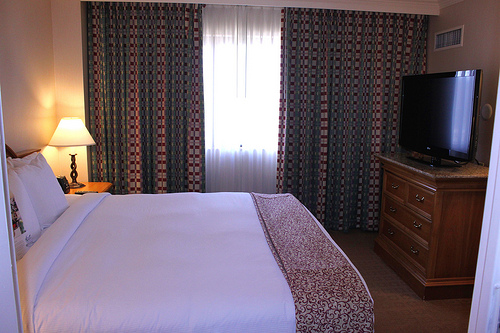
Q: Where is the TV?
A: On the dresser.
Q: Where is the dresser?
A: Under the TV.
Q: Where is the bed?
A: Against the wall.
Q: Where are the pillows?
A: On the bed.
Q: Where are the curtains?
A: On the window.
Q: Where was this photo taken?
A: Hotel room.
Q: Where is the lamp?
A: On the end table.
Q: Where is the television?
A: On top of the dresser.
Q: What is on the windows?
A: Curtains.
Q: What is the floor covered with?
A: Carpet.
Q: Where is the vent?
A: Above the television.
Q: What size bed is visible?
A: Queen.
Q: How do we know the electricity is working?
A: The lamp is on.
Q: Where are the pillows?
A: On the bed.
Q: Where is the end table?
A: Between the bed and windows.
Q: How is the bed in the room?
A: Made up.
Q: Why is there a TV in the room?
A: To entertain hotel guests.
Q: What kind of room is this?
A: Hotel room.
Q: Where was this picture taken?
A: A hotel room.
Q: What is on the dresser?
A: A television.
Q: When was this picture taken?
A: Daytime.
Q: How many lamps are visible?
A: One.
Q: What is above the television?
A: A vent.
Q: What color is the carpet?
A: Brown.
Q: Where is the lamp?
A: By the bed.